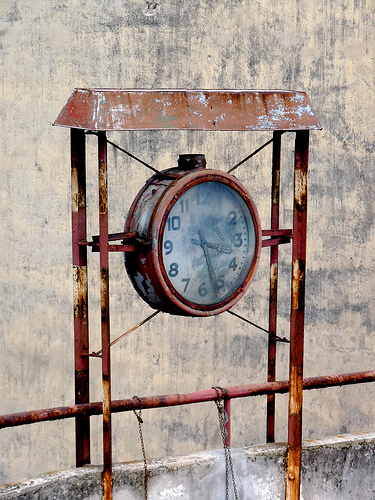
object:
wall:
[0, 0, 375, 499]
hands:
[189, 236, 232, 254]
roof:
[50, 85, 324, 133]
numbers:
[181, 275, 194, 292]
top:
[49, 85, 323, 132]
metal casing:
[50, 87, 322, 498]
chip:
[141, 1, 162, 16]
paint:
[72, 265, 88, 322]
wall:
[4, 430, 374, 499]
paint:
[145, 444, 288, 499]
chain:
[132, 392, 152, 499]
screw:
[285, 470, 297, 483]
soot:
[102, 396, 155, 409]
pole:
[87, 312, 161, 356]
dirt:
[162, 181, 257, 307]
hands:
[199, 227, 219, 292]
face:
[160, 182, 256, 308]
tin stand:
[53, 81, 323, 498]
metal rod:
[283, 129, 310, 498]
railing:
[0, 431, 375, 498]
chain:
[212, 380, 243, 499]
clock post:
[266, 132, 284, 446]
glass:
[194, 207, 217, 234]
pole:
[96, 133, 117, 498]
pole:
[70, 130, 91, 468]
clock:
[156, 175, 260, 312]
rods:
[108, 135, 159, 175]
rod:
[0, 368, 375, 432]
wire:
[138, 419, 152, 498]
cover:
[123, 167, 262, 320]